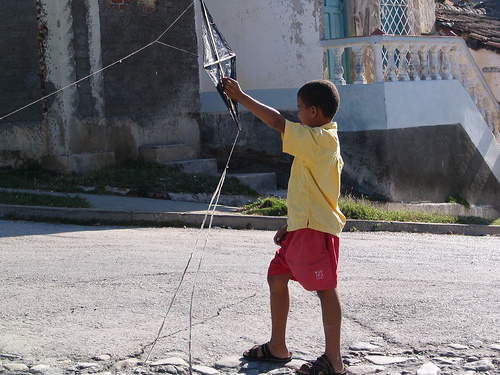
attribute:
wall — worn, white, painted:
[193, 0, 323, 92]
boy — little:
[225, 54, 387, 374]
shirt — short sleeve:
[244, 90, 356, 240]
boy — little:
[263, 78, 391, 270]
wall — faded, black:
[4, 5, 213, 179]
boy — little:
[223, 65, 370, 372]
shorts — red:
[263, 226, 343, 292]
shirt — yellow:
[283, 116, 339, 243]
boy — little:
[221, 75, 349, 375]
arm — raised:
[237, 90, 285, 134]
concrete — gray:
[13, 216, 234, 370]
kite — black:
[164, 4, 265, 135]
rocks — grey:
[343, 298, 417, 373]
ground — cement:
[0, 217, 499, 373]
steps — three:
[150, 137, 285, 196]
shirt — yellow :
[254, 111, 358, 240]